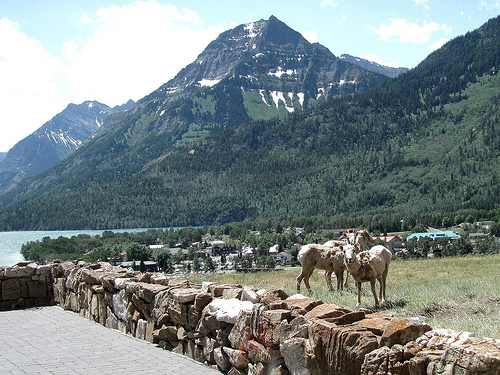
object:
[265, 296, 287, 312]
rocks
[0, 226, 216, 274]
water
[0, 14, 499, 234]
mountain backdrop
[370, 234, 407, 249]
village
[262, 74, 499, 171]
mountain side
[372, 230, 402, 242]
roof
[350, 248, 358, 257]
eyes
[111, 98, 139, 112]
hill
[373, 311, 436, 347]
stone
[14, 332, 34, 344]
brick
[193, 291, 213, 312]
stone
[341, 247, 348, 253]
sheeps eye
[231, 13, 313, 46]
peak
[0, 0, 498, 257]
background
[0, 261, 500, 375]
wall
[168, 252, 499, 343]
field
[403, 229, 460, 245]
building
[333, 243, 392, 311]
animal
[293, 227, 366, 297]
animal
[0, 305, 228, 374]
pavement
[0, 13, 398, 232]
mountain